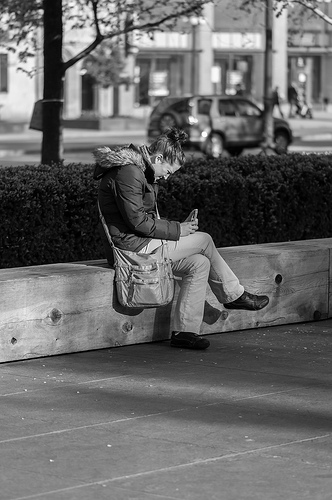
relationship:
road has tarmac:
[7, 140, 330, 154] [5, 124, 329, 151]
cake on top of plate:
[183, 209, 199, 224] [178, 207, 204, 238]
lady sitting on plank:
[91, 126, 269, 350] [0, 235, 330, 364]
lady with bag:
[91, 126, 269, 350] [98, 198, 175, 309]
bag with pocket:
[98, 198, 175, 309] [129, 264, 164, 304]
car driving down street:
[158, 94, 293, 159] [66, 141, 96, 160]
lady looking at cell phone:
[91, 126, 269, 350] [191, 208, 197, 222]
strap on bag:
[92, 156, 170, 256] [110, 243, 174, 306]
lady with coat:
[91, 126, 269, 350] [93, 140, 182, 252]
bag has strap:
[98, 198, 175, 309] [95, 192, 168, 248]